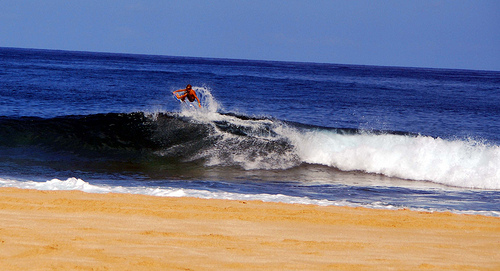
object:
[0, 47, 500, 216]
water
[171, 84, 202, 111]
man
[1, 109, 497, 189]
wave